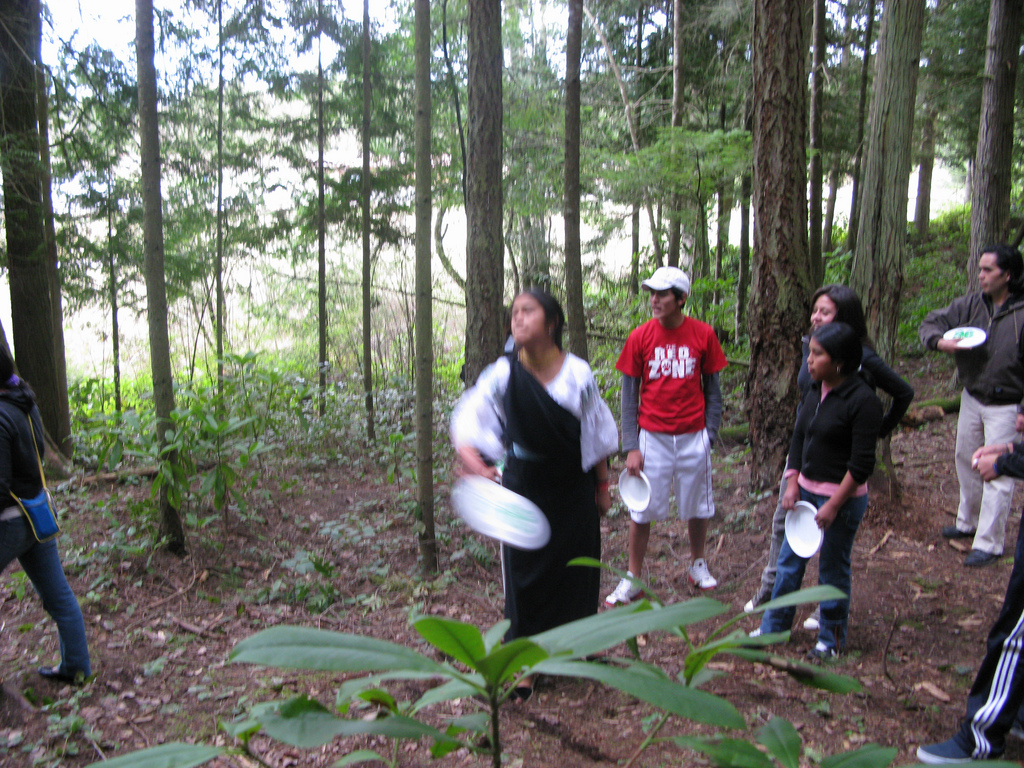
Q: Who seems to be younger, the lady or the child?
A: The child is younger than the lady.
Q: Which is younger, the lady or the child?
A: The child is younger than the lady.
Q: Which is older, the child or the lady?
A: The lady is older than the child.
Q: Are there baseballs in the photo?
A: No, there are no baseballs.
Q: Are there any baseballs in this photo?
A: No, there are no baseballs.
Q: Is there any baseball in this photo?
A: No, there are no baseballs.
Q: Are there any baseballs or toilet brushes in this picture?
A: No, there are no baseballs or toilet brushes.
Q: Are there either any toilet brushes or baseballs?
A: No, there are no baseballs or toilet brushes.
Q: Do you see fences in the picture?
A: No, there are no fences.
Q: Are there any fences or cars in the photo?
A: No, there are no fences or cars.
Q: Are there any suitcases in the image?
A: No, there are no suitcases.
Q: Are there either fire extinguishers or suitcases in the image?
A: No, there are no suitcases or fire extinguishers.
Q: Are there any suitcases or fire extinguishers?
A: No, there are no suitcases or fire extinguishers.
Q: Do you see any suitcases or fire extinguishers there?
A: No, there are no suitcases or fire extinguishers.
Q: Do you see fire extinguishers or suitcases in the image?
A: No, there are no suitcases or fire extinguishers.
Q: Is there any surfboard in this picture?
A: No, there are no surfboards.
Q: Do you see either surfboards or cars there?
A: No, there are no surfboards or cars.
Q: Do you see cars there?
A: No, there are no cars.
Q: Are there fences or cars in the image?
A: No, there are no cars or fences.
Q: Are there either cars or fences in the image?
A: No, there are no cars or fences.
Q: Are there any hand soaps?
A: No, there are no hand soaps.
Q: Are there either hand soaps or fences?
A: No, there are no hand soaps or fences.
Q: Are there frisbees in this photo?
A: Yes, there is a frisbee.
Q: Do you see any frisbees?
A: Yes, there is a frisbee.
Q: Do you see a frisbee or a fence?
A: Yes, there is a frisbee.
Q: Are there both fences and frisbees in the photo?
A: No, there is a frisbee but no fences.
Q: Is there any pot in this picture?
A: No, there are no pots.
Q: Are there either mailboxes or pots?
A: No, there are no pots or mailboxes.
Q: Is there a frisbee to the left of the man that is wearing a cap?
A: Yes, there is a frisbee to the left of the man.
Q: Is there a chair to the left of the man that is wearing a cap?
A: No, there is a frisbee to the left of the man.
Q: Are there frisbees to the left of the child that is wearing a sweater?
A: Yes, there is a frisbee to the left of the child.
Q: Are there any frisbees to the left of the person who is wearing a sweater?
A: Yes, there is a frisbee to the left of the child.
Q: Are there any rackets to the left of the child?
A: No, there is a frisbee to the left of the child.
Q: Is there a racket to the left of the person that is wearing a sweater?
A: No, there is a frisbee to the left of the child.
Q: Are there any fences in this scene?
A: No, there are no fences.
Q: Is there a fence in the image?
A: No, there are no fences.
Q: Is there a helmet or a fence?
A: No, there are no fences or helmets.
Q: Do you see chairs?
A: No, there are no chairs.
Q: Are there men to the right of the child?
A: Yes, there is a man to the right of the child.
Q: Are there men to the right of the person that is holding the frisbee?
A: Yes, there is a man to the right of the child.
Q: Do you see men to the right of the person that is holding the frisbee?
A: Yes, there is a man to the right of the child.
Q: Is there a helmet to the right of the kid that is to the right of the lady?
A: No, there is a man to the right of the child.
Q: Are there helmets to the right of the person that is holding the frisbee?
A: No, there is a man to the right of the child.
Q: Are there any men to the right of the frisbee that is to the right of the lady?
A: Yes, there is a man to the right of the frisbee.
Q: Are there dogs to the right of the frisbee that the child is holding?
A: No, there is a man to the right of the frisbee.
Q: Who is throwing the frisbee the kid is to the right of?
A: The man is throwing the frisbee.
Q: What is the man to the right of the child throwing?
A: The man is throwing the frisbee.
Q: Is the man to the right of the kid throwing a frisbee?
A: Yes, the man is throwing a frisbee.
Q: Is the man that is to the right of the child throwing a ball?
A: No, the man is throwing a frisbee.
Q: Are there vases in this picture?
A: No, there are no vases.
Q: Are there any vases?
A: No, there are no vases.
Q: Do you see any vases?
A: No, there are no vases.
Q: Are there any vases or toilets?
A: No, there are no vases or toilets.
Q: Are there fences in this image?
A: No, there are no fences.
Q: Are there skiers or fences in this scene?
A: No, there are no fences or skiers.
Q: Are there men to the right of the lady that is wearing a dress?
A: Yes, there is a man to the right of the lady.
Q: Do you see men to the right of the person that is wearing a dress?
A: Yes, there is a man to the right of the lady.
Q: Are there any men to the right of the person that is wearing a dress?
A: Yes, there is a man to the right of the lady.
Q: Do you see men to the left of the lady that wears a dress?
A: No, the man is to the right of the lady.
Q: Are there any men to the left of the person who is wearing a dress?
A: No, the man is to the right of the lady.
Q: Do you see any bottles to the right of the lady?
A: No, there is a man to the right of the lady.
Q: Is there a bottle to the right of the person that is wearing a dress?
A: No, there is a man to the right of the lady.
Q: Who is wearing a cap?
A: The man is wearing a cap.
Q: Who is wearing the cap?
A: The man is wearing a cap.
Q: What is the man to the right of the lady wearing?
A: The man is wearing a cap.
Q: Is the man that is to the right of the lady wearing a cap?
A: Yes, the man is wearing a cap.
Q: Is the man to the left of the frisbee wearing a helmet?
A: No, the man is wearing a cap.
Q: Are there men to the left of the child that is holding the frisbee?
A: Yes, there is a man to the left of the child.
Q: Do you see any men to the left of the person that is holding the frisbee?
A: Yes, there is a man to the left of the child.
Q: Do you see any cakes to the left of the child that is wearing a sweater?
A: No, there is a man to the left of the child.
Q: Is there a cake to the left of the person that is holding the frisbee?
A: No, there is a man to the left of the child.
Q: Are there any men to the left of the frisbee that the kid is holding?
A: Yes, there is a man to the left of the frisbee.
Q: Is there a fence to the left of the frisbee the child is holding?
A: No, there is a man to the left of the frisbee.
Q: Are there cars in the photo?
A: No, there are no cars.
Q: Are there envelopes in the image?
A: No, there are no envelopes.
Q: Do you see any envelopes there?
A: No, there are no envelopes.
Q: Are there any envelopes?
A: No, there are no envelopes.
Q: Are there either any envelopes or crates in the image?
A: No, there are no envelopes or crates.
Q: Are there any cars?
A: No, there are no cars.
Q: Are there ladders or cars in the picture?
A: No, there are no cars or ladders.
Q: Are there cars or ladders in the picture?
A: No, there are no cars or ladders.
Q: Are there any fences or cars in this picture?
A: No, there are no cars or fences.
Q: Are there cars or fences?
A: No, there are no cars or fences.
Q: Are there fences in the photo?
A: No, there are no fences.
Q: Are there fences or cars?
A: No, there are no fences or cars.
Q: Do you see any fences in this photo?
A: No, there are no fences.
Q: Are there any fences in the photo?
A: No, there are no fences.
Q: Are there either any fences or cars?
A: No, there are no fences or cars.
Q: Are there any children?
A: Yes, there is a child.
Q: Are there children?
A: Yes, there is a child.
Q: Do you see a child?
A: Yes, there is a child.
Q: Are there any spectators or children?
A: Yes, there is a child.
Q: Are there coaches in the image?
A: No, there are no coaches.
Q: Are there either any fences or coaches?
A: No, there are no coaches or fences.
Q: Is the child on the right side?
A: Yes, the child is on the right of the image.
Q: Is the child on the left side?
A: No, the child is on the right of the image.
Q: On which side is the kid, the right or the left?
A: The kid is on the right of the image.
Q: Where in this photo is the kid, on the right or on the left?
A: The kid is on the right of the image.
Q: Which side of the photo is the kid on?
A: The kid is on the right of the image.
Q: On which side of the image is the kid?
A: The kid is on the right of the image.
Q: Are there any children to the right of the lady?
A: Yes, there is a child to the right of the lady.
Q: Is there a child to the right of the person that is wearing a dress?
A: Yes, there is a child to the right of the lady.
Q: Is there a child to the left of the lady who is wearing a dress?
A: No, the child is to the right of the lady.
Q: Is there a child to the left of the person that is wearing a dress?
A: No, the child is to the right of the lady.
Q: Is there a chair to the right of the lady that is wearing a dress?
A: No, there is a child to the right of the lady.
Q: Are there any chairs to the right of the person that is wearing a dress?
A: No, there is a child to the right of the lady.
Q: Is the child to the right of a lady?
A: Yes, the child is to the right of a lady.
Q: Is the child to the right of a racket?
A: No, the child is to the right of a lady.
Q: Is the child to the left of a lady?
A: No, the child is to the right of a lady.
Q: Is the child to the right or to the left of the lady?
A: The child is to the right of the lady.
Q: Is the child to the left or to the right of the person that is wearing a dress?
A: The child is to the right of the lady.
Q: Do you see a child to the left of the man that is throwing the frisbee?
A: Yes, there is a child to the left of the man.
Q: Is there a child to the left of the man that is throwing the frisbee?
A: Yes, there is a child to the left of the man.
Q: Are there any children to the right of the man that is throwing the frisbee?
A: No, the child is to the left of the man.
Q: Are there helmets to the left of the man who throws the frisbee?
A: No, there is a child to the left of the man.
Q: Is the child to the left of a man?
A: Yes, the child is to the left of a man.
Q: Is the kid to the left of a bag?
A: No, the kid is to the left of a man.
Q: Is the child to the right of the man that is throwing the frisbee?
A: No, the child is to the left of the man.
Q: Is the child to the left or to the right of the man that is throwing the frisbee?
A: The child is to the left of the man.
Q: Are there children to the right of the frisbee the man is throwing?
A: Yes, there is a child to the right of the frisbee.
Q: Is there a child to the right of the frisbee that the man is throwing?
A: Yes, there is a child to the right of the frisbee.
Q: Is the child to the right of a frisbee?
A: Yes, the child is to the right of a frisbee.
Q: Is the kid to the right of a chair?
A: No, the kid is to the right of a frisbee.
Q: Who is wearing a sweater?
A: The child is wearing a sweater.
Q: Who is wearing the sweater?
A: The child is wearing a sweater.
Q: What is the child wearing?
A: The child is wearing a sweater.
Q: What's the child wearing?
A: The child is wearing a sweater.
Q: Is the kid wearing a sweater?
A: Yes, the kid is wearing a sweater.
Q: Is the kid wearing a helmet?
A: No, the kid is wearing a sweater.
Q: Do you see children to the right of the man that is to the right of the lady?
A: Yes, there is a child to the right of the man.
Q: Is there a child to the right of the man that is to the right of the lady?
A: Yes, there is a child to the right of the man.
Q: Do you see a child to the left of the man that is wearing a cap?
A: No, the child is to the right of the man.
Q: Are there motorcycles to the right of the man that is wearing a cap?
A: No, there is a child to the right of the man.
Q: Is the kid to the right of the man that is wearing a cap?
A: Yes, the kid is to the right of the man.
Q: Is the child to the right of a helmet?
A: No, the child is to the right of the man.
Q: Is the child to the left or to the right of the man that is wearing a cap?
A: The child is to the right of the man.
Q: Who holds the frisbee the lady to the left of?
A: The child holds the frisbee.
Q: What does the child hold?
A: The child holds the frisbee.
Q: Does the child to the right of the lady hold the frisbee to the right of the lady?
A: Yes, the kid holds the frisbee.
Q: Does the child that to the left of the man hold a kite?
A: No, the child holds the frisbee.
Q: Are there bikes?
A: No, there are no bikes.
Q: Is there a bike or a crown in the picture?
A: No, there are no bikes or crowns.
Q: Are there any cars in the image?
A: No, there are no cars.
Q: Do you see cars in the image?
A: No, there are no cars.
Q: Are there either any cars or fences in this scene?
A: No, there are no cars or fences.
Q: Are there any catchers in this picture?
A: No, there are no catchers.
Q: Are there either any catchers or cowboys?
A: No, there are no catchers or cowboys.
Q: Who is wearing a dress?
A: The lady is wearing a dress.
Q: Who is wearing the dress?
A: The lady is wearing a dress.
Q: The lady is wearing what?
A: The lady is wearing a dress.